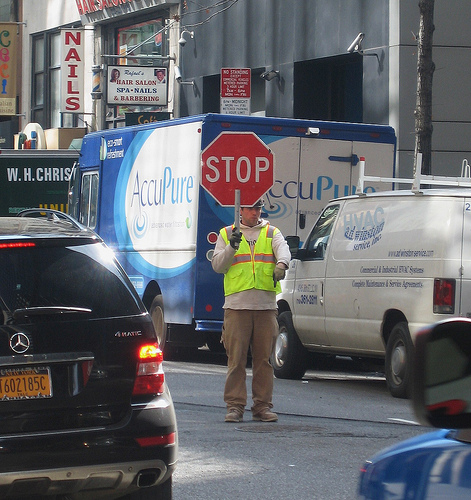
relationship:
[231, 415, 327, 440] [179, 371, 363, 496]
manhole cover on street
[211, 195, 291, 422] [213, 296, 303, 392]
man wearing pants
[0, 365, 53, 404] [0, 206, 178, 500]
license plate in front of suv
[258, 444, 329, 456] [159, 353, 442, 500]
asphalt of asphalt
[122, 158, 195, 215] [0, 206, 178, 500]
logo on suv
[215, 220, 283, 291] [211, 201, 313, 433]
vest on man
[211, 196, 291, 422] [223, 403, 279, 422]
man wearing shoes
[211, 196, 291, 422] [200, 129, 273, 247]
man holding sign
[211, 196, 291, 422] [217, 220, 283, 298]
man wearing a vest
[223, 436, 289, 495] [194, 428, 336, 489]
patch of asphalt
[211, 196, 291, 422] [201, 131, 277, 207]
man holding stop sign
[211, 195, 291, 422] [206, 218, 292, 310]
man wears sweatshirt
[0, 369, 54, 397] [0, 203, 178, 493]
license plate on suv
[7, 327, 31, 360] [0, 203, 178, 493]
metal logo on suv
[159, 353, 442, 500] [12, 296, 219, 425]
asphalt full of traffic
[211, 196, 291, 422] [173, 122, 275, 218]
man holding stop sign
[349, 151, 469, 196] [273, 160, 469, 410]
rack on van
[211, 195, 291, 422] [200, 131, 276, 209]
man holding sign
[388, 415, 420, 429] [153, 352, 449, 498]
line painted on road